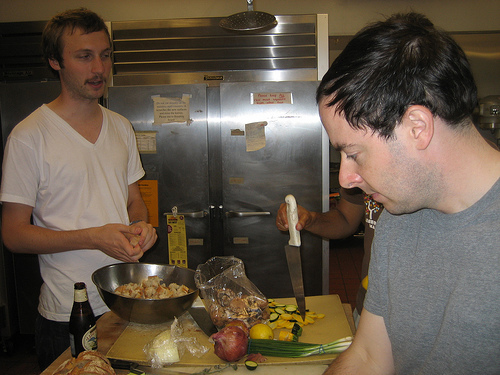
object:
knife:
[284, 194, 306, 321]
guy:
[275, 187, 386, 331]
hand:
[276, 202, 312, 231]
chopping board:
[101, 294, 354, 368]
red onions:
[223, 318, 250, 338]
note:
[245, 121, 267, 151]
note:
[153, 96, 190, 123]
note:
[167, 214, 188, 268]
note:
[137, 179, 159, 227]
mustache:
[83, 76, 106, 85]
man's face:
[61, 33, 112, 98]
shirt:
[335, 182, 384, 315]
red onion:
[210, 326, 248, 362]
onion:
[209, 322, 249, 362]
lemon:
[250, 323, 274, 340]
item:
[211, 303, 225, 326]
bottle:
[68, 282, 98, 355]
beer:
[68, 282, 98, 356]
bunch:
[248, 336, 354, 359]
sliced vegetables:
[268, 298, 324, 328]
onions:
[216, 316, 261, 373]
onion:
[149, 330, 181, 363]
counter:
[41, 302, 356, 375]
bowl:
[90, 262, 201, 326]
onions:
[249, 331, 354, 361]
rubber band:
[319, 344, 326, 355]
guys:
[313, 12, 500, 375]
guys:
[1, 11, 157, 370]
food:
[114, 275, 194, 300]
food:
[209, 288, 270, 329]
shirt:
[0, 103, 146, 324]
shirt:
[359, 173, 500, 375]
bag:
[194, 255, 270, 331]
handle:
[284, 194, 301, 248]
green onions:
[245, 338, 354, 358]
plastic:
[143, 325, 211, 368]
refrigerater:
[0, 19, 331, 300]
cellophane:
[142, 311, 216, 369]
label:
[67, 325, 98, 356]